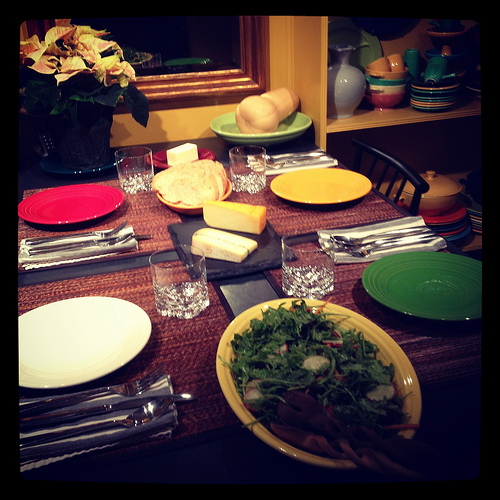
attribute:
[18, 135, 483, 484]
table — set, dark, wooden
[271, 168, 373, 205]
plate — yellow, empty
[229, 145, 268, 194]
glass — clear, fancy, empty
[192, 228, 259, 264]
cheese — sliced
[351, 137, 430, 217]
chair — black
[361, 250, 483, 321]
plate — green, empty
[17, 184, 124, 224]
plate — red, empty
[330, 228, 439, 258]
utensils — silver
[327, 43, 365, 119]
vase — grey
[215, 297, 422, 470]
bowl — oval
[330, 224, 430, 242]
spoon — silver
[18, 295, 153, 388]
plate — white, empty